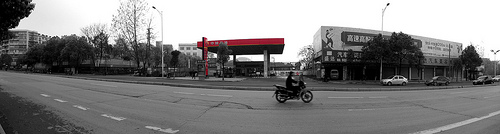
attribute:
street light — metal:
[151, 2, 162, 12]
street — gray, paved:
[39, 73, 496, 127]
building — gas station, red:
[234, 56, 270, 75]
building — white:
[0, 30, 43, 57]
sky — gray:
[179, 1, 330, 27]